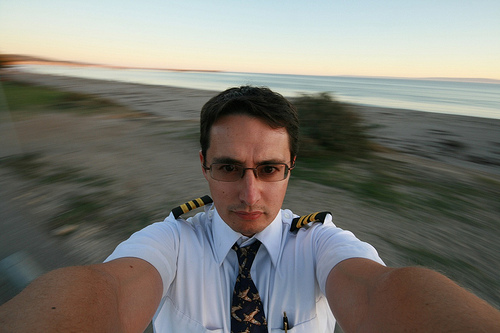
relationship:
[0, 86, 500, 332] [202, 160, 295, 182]
man wears glasses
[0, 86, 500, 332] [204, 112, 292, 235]
man has face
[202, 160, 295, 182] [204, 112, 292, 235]
glasses worn on face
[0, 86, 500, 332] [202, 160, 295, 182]
man wearing glasses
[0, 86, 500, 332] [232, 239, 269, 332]
man wearing tie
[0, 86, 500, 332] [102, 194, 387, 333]
man wearing shirt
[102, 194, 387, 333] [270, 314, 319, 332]
shirt has pocket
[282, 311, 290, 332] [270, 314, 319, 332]
pen in pocket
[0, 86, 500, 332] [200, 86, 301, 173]
man has hair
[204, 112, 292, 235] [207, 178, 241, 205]
face has cheek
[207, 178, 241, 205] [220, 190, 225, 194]
cheek has mole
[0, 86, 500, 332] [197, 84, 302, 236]
man has head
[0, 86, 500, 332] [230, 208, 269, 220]
man has mouth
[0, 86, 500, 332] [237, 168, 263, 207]
man has nose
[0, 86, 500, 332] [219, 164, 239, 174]
man has eye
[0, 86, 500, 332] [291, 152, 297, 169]
man has ear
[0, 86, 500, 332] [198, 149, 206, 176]
man has ear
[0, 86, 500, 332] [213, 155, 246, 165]
man has eyebrow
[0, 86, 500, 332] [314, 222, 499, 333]
man has arm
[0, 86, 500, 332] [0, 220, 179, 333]
man has arm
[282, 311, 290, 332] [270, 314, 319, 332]
pen inside pocket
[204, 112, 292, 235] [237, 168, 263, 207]
face has nose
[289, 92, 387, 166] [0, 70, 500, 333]
bush growing on beach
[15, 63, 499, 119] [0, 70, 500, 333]
water near beach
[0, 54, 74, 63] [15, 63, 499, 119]
hillside behind water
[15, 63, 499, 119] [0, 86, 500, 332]
water behind man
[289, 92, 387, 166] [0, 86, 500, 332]
bush behind man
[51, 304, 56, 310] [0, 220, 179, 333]
freckle on arm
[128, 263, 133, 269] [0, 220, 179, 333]
freckle on arm